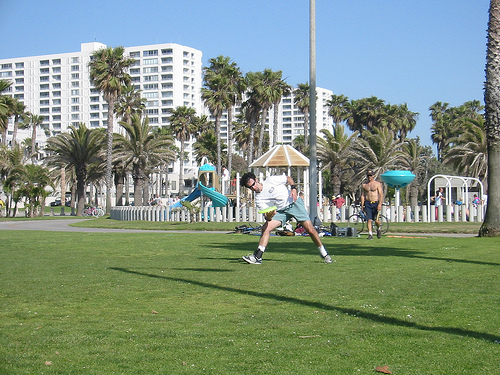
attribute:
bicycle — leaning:
[80, 203, 105, 218]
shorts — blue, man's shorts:
[363, 201, 383, 221]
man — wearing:
[205, 144, 318, 286]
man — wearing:
[224, 159, 332, 281]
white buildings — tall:
[1, 39, 339, 223]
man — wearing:
[235, 170, 333, 267]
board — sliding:
[168, 182, 228, 210]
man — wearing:
[224, 158, 309, 217]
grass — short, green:
[143, 288, 293, 337]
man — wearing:
[235, 174, 333, 276]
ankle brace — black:
[249, 243, 266, 261]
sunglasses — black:
[242, 177, 257, 189]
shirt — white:
[241, 178, 296, 210]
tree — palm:
[45, 122, 116, 219]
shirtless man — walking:
[358, 169, 385, 238]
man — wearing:
[232, 169, 341, 266]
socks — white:
[257, 244, 329, 255]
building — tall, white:
[5, 47, 215, 180]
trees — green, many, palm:
[2, 70, 129, 212]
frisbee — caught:
[257, 204, 281, 218]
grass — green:
[73, 185, 464, 357]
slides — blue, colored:
[183, 164, 230, 204]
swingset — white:
[423, 173, 483, 228]